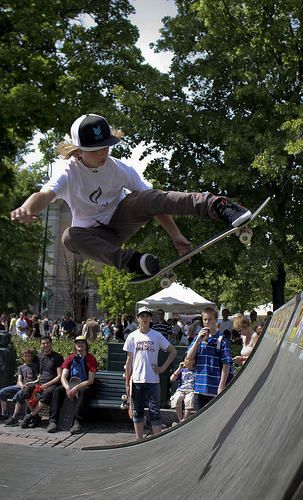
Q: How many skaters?
A: One.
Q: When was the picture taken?
A: Daytime.